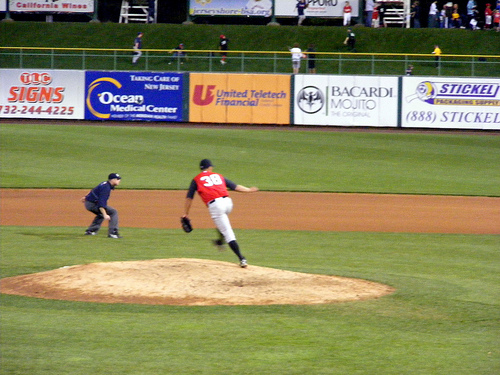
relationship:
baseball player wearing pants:
[179, 158, 260, 268] [210, 197, 241, 251]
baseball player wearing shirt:
[172, 152, 263, 279] [84, 184, 113, 205]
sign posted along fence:
[399, 72, 498, 134] [0, 45, 500, 132]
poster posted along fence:
[289, 74, 399, 128] [0, 45, 500, 132]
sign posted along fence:
[188, 72, 293, 125] [0, 45, 500, 132]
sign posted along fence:
[85, 71, 187, 121] [0, 45, 500, 132]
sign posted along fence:
[0, 67, 83, 122] [0, 45, 500, 132]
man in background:
[432, 46, 443, 67] [1, 0, 499, 144]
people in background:
[285, 41, 303, 71] [1, 0, 499, 144]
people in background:
[341, 30, 357, 47] [1, 0, 499, 144]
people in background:
[213, 28, 229, 61] [1, 0, 499, 144]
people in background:
[132, 27, 146, 60] [1, 0, 499, 144]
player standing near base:
[80, 172, 124, 238] [109, 259, 146, 281]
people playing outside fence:
[132, 32, 145, 64] [0, 45, 500, 132]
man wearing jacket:
[432, 45, 441, 66] [431, 47, 438, 57]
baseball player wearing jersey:
[179, 158, 260, 268] [184, 173, 236, 209]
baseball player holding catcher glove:
[172, 152, 263, 279] [177, 215, 195, 235]